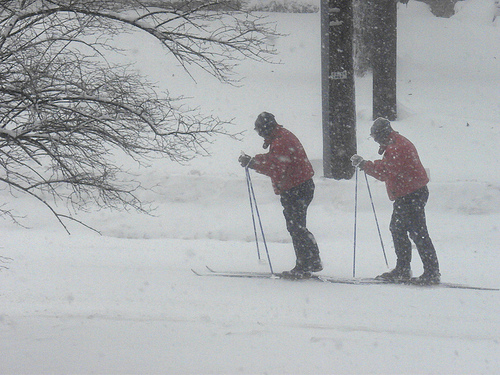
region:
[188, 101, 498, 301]
two people cross country skiing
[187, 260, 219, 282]
tips of a pair of skis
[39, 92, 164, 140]
tree branch growing in downward arch shape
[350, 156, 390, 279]
set of ski poles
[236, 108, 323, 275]
person wearing thick red winter jacket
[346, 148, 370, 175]
person's left hand wearing a glove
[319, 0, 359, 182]
vertical metal utility pole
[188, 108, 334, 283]
person on snow skis propelling himself forward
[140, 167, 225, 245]
snowbank with steep edge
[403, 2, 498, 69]
white snow piled on a slope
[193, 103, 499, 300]
two people on skis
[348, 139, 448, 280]
red jacket and black pants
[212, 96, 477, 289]
two people wearing identical outfits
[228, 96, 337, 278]
slightly leaning forward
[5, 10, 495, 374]
snow covering the ground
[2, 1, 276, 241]
tree branches with no leaves on them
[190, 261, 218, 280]
front end of the skis are bent upwards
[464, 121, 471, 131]
small black speck on the snow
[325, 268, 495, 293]
set of long skis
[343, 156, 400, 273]
two skinny ski poles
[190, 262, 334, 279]
a pair of snow covered skis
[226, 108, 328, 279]
a man wearing ski gear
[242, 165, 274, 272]
a set of skiing poles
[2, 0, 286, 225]
the snow covered branches of a tree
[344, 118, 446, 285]
a man wearing a red jacket and black pants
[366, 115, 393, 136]
a grey woolly hat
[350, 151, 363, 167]
skiing gloves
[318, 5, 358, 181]
a thick tree trunk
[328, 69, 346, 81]
a black and white sign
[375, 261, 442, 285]
feet attached to skis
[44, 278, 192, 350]
heavy snow on the ground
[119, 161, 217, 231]
falling snow in the air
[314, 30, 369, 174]
large black post in the snow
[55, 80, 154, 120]
snow covering bare trees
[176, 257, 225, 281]
edge of snow ski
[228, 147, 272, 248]
ski pole in skier's hand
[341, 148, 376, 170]
white glove on skier's hand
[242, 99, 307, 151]
cap on skier's head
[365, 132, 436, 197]
skier wearing red jacket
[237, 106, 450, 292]
skiers marching on the snow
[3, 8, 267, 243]
the trees are bare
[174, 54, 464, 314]
two people are skiing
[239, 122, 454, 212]
the jackets are red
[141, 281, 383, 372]
snow on the ground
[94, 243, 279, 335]
snow on the ground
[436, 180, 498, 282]
snow on the ground